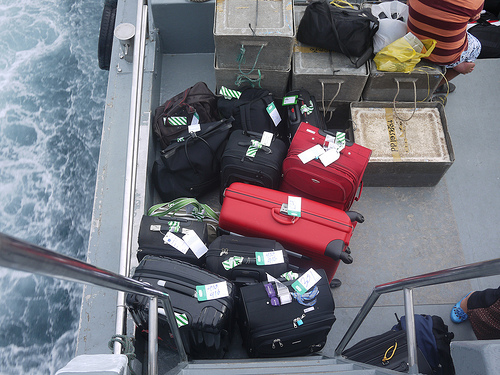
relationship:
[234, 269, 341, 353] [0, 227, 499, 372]
luggage at bottom of stairs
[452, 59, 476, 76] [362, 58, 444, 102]
foot of girl by luggage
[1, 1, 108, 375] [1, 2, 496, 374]
water on side of boat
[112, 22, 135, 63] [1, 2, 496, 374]
cup sitting on boat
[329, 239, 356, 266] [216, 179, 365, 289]
wheel on luggage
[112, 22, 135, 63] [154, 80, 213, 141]
portion of water near luggage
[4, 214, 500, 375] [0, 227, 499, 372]
railing by stairs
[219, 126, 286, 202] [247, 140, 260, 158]
suit case has a flag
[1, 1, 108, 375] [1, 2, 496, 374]
water outside of boat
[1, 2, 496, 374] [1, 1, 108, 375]
boat on water